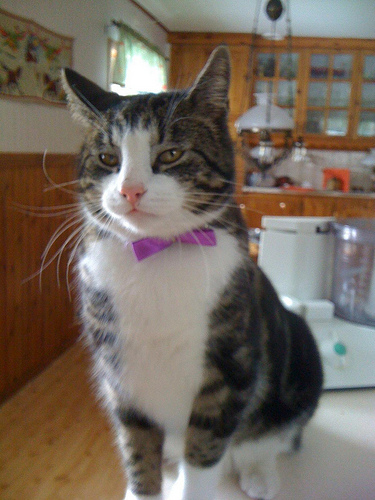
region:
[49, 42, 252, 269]
a head of a cat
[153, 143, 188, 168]
the eye of a cat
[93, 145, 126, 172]
the eye of a cat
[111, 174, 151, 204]
the nose of a cat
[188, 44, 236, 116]
an ear of a cat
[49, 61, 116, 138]
an ear of a cat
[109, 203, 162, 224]
a mouth of a cat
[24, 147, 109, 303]
the whiskers of a cat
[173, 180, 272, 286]
the whiskers of a cat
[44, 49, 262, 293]
a cat wearing a purple bow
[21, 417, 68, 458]
Part of the floor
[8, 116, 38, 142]
Part of the wall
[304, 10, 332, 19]
Part of the ceiling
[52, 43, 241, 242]
The head of the cat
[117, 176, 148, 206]
The nose of the cat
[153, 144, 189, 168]
The left eye of the cat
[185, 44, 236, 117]
The left ear of the cat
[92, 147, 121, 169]
The right ear of the cat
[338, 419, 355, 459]
Part of the table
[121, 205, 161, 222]
The mouth of the cat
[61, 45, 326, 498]
a gray and white cat on the kitchen table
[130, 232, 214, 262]
a purple bow tie on the cat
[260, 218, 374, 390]
a white food processor behind the cat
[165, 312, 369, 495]
a white table under the cat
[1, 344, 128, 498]
yellow pine hardwood floors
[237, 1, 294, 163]
a hanging kitchen light fixture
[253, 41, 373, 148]
upper cabinets in the kitchen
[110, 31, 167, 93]
a kitchen window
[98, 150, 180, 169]
the cat's eyes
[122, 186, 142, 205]
the cat's pink nose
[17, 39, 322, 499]
brown and black tabby with white chest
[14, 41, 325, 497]
cat wearing a purple ribbon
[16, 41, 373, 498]
cat on kitchen counter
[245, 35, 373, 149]
upper cabinets with glass doors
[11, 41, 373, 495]
cuisinart behind cat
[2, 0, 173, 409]
wood panel wall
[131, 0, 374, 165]
light fixture hangs from ceiling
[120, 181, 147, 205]
pink cat nose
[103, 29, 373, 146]
window left of cabinets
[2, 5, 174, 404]
top half of wall is white, bottom half is unpainted wood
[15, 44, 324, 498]
Cat wearing purple bow tie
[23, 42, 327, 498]
Cat on a table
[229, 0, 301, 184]
lamp hanging from ceiling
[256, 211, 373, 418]
Large blender on a table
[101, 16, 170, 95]
Curtains on the window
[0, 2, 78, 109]
Framed picture hanging on a wall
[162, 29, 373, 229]
Brown Kitchen Cabinets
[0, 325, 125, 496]
Light Brown Hardwood floor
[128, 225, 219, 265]
Purple Bow Tie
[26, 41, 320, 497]
Large white and gray striped cat